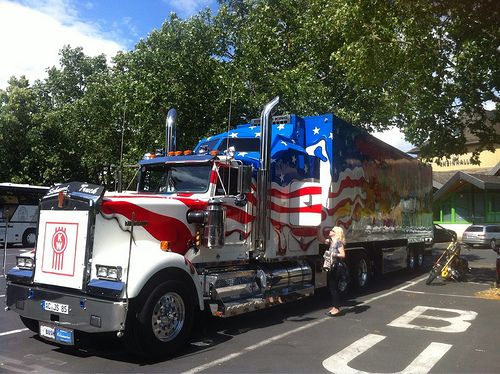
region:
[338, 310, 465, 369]
part of the road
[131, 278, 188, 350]
front wheel of the trailer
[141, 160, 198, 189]
front wheel of the trailer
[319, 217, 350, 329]
a woman by the door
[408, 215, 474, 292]
a tilted motorbike by the trailer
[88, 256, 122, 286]
left headlight of the trailer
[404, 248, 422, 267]
two hind wheels of the trailer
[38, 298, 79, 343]
number plate of the trailer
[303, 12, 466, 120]
part of tree branches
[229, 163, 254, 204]
left side mirror of the trailer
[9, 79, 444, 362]
A red, white and blue semi truck.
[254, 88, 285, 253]
Chrome exhaust pipes on side of truck's cab.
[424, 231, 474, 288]
Motorcycle parked next to semi truck.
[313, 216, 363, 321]
Woman standing next to semi truck.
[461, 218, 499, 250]
Gray car parked in front of building.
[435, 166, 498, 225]
Front of green colored building.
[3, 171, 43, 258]
Portion of bus parked in parking lot.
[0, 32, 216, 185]
Top of trees growing in parking lot.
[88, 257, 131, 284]
Headlights on front of semi truck.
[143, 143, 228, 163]
Running lights mounted on top of semi truck's cab.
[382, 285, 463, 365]
a part of the road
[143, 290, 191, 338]
front wheel of a trailer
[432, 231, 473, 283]
a tilted motor bike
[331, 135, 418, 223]
wall of the body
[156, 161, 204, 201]
front window of the trailer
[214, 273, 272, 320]
part of a staircase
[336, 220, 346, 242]
white hair of the woman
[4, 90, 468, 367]
truck parked in a lot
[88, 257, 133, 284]
front headlights on a vehicle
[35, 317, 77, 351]
front licence plates on a vehicle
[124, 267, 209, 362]
front wheel on a vehicle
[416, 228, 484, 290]
motorcycle parked near a truck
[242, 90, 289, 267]
exhaust pipe of a vehicle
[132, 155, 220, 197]
front windshield of a vehicle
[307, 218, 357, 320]
person with black pant standing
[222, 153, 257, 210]
side rear view mirror on a vehicle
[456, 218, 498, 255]
car parked near a building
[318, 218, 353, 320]
a woman is reaching into a truck compartment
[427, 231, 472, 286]
a dirt bike parked near a truck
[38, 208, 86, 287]
a kw grill cover on truck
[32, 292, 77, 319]
truck license plate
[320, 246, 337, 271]
woman holding a purse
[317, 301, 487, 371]
a B U painted in a parking spot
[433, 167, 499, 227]
a building with green trim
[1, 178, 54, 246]
a bus parked in a parking lot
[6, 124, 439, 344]
american flag painted truck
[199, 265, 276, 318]
truck step boards